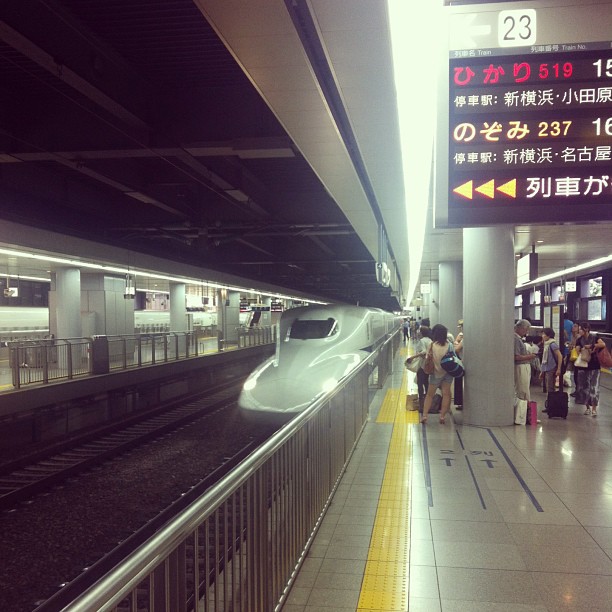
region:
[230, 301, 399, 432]
White high speed train.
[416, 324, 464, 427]
Woman carrying two bags.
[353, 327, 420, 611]
Yellow stripe painted on train platform.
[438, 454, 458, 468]
Black arrow painted on gray floor.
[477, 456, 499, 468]
Black arrow painted on gray floor.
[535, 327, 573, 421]
Woman pushing a black suitcase.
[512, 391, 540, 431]
Two paper bags sitting on the ground.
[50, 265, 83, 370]
White concrete support post.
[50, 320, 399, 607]
Black fence with silver railing.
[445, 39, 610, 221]
Black informational sign with yellow arrows.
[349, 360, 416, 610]
long yellow stripe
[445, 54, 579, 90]
red symbols on a sign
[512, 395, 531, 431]
white bag on the floor next to a pillar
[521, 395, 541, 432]
red bag next to a white bag on the floor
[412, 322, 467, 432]
person wearing blue shorts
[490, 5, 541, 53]
number 23 above a large sign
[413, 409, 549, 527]
three black parallel stripes on the floor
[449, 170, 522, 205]
three yellow arrows pointing left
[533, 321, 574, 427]
person with suitcase on the floor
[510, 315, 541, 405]
man leaning against a pillar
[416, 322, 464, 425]
a person walking on a sidewalk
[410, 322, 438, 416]
a person walking on a sidewalk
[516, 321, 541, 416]
a person walking on a sidewalk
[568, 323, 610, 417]
a person walking on a sidewalk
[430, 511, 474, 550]
a tile in a floor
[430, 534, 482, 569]
a tile in a floor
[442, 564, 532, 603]
a tile in a floor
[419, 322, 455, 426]
a woman is standing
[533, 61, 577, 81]
The red numbers on the sign.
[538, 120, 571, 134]
The yellow numbers on the sign.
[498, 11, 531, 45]
The numbers above the sign.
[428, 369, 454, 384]
The shorts the lady is wearing.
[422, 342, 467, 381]
The two bags the lady is carrying.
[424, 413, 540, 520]
The blue lines on the platform.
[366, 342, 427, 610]
The yellow lines on the platform.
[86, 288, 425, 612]
The barrier gate near the platform.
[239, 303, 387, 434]
The train on the tracks.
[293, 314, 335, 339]
The front window of the train.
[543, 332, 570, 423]
a person at the train station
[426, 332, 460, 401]
a person at the train station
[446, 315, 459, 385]
a person at the train station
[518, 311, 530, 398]
a person at the train station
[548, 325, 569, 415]
a person at the train station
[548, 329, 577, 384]
a person at the train station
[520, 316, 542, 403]
a person at the train station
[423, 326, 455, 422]
a person is standing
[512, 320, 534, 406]
a person is standing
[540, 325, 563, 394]
a person is standing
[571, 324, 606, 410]
a person is standing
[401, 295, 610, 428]
people waiting for train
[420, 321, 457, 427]
A person is standing up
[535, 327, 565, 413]
A person is standing up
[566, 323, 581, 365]
A person is standing up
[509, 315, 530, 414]
A person is standing up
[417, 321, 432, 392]
A person is standing up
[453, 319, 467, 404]
A person is standing up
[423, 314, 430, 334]
A person is standing up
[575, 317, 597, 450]
a person on the sidewalk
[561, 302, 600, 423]
a person on the sidewalk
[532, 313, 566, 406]
a person on the sidewalk